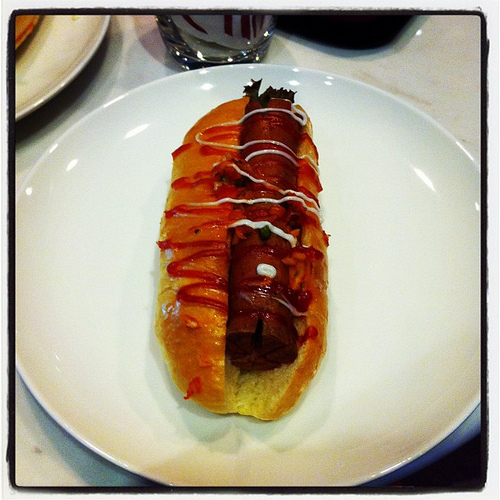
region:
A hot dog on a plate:
[1, 85, 491, 470]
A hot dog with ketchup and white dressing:
[162, 90, 350, 434]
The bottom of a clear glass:
[155, 13, 283, 63]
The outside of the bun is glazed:
[160, 105, 234, 377]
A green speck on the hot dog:
[258, 220, 271, 240]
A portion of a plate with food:
[15, 13, 115, 129]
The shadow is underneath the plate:
[12, 12, 121, 121]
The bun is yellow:
[166, 370, 310, 420]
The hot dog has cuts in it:
[227, 323, 299, 370]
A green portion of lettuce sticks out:
[248, 80, 294, 100]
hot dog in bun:
[222, 98, 302, 373]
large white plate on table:
[13, 60, 480, 489]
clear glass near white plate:
[152, 9, 278, 70]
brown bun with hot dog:
[153, 93, 330, 422]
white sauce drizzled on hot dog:
[188, 100, 329, 330]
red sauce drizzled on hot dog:
[156, 123, 331, 350]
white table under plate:
[13, 12, 482, 488]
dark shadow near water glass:
[271, 10, 420, 52]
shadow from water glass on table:
[133, 12, 184, 72]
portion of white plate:
[11, 8, 111, 124]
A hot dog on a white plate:
[18, 63, 495, 487]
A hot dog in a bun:
[163, 80, 324, 417]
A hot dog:
[229, 85, 299, 372]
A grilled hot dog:
[228, 85, 306, 372]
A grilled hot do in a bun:
[154, 86, 334, 422]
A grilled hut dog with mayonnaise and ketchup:
[158, 85, 329, 420]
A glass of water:
[154, 0, 274, 75]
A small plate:
[0, 15, 112, 122]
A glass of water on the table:
[158, 0, 273, 70]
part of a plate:
[271, 338, 340, 400]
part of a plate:
[347, 365, 393, 401]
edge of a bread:
[218, 365, 228, 378]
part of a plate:
[337, 391, 370, 446]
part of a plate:
[382, 327, 408, 362]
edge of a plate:
[355, 450, 420, 480]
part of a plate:
[347, 373, 383, 420]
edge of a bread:
[215, 373, 230, 396]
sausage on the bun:
[235, 103, 300, 375]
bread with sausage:
[161, 100, 315, 412]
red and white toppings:
[177, 110, 325, 328]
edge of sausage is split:
[221, 325, 288, 369]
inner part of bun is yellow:
[222, 348, 283, 412]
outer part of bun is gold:
[157, 100, 249, 397]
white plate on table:
[21, 63, 480, 485]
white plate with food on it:
[21, 58, 491, 486]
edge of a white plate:
[0, 10, 114, 119]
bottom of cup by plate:
[155, 17, 275, 65]